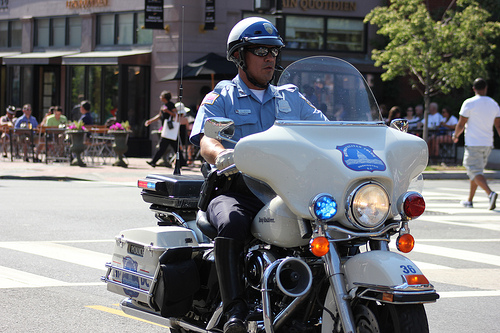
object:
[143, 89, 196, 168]
person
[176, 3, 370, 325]
officer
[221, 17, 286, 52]
helmet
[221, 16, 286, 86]
head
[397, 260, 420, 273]
number 36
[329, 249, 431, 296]
bumper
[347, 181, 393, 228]
light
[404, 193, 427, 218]
light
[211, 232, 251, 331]
boot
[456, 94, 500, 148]
shirt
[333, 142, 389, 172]
shield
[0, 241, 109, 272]
line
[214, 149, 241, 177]
glove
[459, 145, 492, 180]
shorts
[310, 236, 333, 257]
orange headlight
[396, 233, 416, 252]
orange headlight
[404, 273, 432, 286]
orange headlight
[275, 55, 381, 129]
windshield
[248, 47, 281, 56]
goggles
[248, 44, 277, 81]
face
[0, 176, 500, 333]
ground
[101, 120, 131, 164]
planter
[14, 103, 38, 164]
people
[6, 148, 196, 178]
sidewalk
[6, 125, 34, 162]
tables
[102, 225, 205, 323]
container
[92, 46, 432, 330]
motorcycle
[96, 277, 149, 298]
bars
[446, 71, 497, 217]
pedestrian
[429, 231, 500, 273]
white lines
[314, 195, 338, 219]
light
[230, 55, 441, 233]
hood